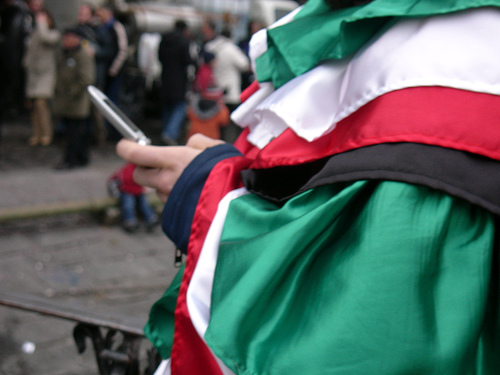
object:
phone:
[87, 84, 154, 145]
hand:
[117, 133, 227, 205]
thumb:
[184, 132, 227, 151]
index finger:
[115, 138, 183, 168]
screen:
[103, 97, 140, 133]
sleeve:
[162, 141, 244, 255]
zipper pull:
[174, 246, 183, 268]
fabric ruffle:
[255, 1, 500, 90]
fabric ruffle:
[229, 4, 500, 149]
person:
[108, 159, 160, 235]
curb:
[0, 192, 165, 231]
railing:
[0, 291, 163, 374]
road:
[1, 218, 187, 374]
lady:
[23, 9, 62, 148]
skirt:
[26, 66, 57, 97]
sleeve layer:
[203, 180, 499, 374]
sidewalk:
[1, 109, 172, 210]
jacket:
[187, 97, 230, 141]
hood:
[193, 96, 219, 121]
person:
[116, 1, 500, 374]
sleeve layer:
[171, 156, 257, 373]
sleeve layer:
[186, 184, 254, 374]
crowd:
[1, 1, 268, 173]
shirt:
[108, 163, 144, 194]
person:
[53, 28, 100, 168]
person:
[158, 20, 191, 146]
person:
[93, 5, 129, 143]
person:
[201, 26, 250, 146]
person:
[65, 4, 97, 44]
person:
[237, 18, 267, 91]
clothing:
[143, 1, 500, 373]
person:
[184, 81, 230, 140]